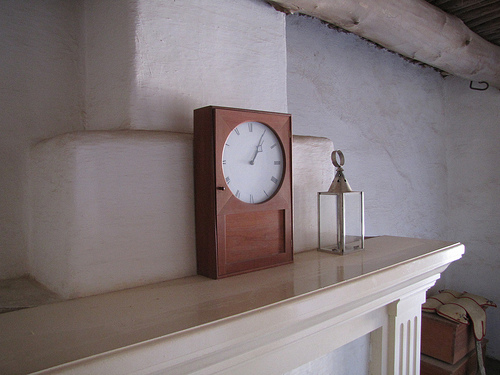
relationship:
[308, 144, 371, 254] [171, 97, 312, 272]
decoration by clock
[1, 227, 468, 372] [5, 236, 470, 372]
mantle of fireplace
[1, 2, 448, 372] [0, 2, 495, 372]
wall of house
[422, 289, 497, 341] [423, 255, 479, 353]
boes in corner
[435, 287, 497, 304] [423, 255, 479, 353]
boes in corner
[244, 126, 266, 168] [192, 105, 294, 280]
handles of clock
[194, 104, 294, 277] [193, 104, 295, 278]
clock on frame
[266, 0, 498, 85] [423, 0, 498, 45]
log on roof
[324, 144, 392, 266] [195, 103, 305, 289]
thing on side of clock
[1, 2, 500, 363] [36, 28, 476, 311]
wall in building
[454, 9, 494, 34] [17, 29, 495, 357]
ceiling in photo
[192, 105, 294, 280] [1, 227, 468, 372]
clock on mantle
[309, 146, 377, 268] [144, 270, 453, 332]
metal on top of mantle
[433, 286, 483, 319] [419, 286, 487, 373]
mats on top of box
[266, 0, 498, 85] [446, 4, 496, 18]
log on ceiling